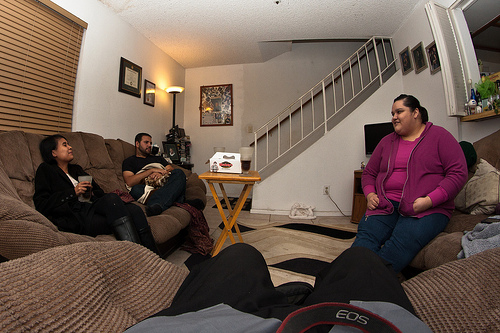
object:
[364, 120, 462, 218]
shirt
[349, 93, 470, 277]
woman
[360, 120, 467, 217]
jacket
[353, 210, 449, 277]
jeans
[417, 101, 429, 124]
pony tail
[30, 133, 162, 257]
person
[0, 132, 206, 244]
couch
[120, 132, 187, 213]
man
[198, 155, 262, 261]
table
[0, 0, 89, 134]
curtain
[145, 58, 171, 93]
reflection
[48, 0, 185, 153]
wall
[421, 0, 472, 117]
shutter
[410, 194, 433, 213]
hand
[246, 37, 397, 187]
railing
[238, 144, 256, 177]
glass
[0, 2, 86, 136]
window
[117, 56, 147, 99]
picture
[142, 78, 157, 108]
picture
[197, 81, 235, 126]
picture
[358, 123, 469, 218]
purple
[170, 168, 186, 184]
knees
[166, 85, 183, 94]
lamp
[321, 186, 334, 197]
outlet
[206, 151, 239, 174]
food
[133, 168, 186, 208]
jeans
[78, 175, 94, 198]
cup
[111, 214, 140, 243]
boots